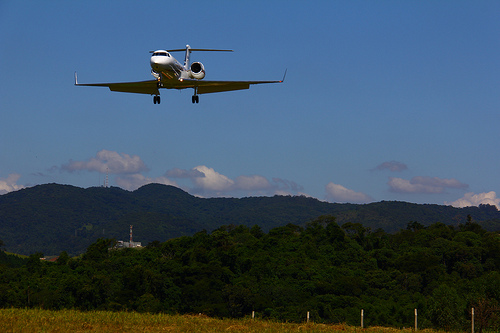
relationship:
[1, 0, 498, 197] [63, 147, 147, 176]
blue sky has clouds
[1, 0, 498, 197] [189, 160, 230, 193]
blue sky has clouds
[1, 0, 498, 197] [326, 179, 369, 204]
blue sky has clouds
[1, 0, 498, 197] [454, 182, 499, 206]
blue sky has clouds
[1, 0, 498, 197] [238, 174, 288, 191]
blue sky has clouds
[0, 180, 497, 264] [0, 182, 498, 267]
hill has trees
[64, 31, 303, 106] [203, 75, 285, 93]
plane has wing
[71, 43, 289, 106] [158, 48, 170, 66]
plane has nose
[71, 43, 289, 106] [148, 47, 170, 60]
plane has windshield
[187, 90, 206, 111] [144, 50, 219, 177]
wheel of plane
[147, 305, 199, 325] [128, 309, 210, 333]
grass on ground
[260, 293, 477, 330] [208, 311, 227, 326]
poles on ground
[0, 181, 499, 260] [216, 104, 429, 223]
hill in back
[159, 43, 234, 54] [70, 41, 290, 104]
tail of plane